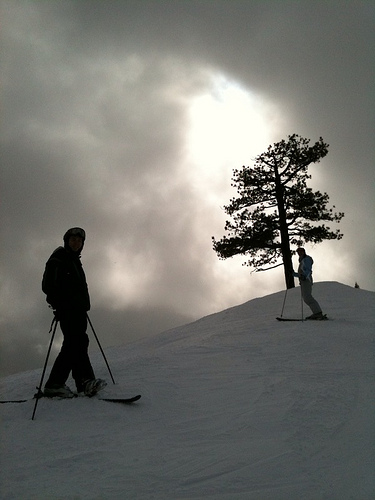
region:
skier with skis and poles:
[26, 219, 156, 425]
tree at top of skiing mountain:
[227, 140, 339, 288]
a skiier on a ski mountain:
[259, 242, 335, 329]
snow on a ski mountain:
[214, 399, 297, 466]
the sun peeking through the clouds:
[156, 69, 300, 198]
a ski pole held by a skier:
[20, 308, 76, 426]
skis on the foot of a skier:
[41, 381, 143, 411]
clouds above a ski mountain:
[126, 248, 195, 308]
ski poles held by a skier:
[277, 267, 310, 317]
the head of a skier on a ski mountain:
[58, 227, 93, 261]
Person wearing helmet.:
[50, 219, 98, 248]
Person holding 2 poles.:
[8, 369, 131, 387]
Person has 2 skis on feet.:
[57, 373, 163, 418]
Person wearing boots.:
[43, 372, 132, 399]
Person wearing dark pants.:
[54, 349, 132, 385]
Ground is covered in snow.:
[169, 407, 281, 495]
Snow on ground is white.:
[177, 400, 282, 471]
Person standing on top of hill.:
[274, 251, 346, 349]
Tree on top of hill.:
[242, 247, 342, 317]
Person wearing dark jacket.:
[39, 237, 111, 321]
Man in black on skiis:
[8, 212, 147, 413]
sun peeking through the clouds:
[185, 87, 274, 175]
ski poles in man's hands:
[15, 306, 123, 437]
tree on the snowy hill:
[208, 128, 353, 306]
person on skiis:
[264, 245, 336, 329]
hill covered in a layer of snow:
[116, 269, 373, 362]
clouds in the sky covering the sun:
[4, 30, 365, 277]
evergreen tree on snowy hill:
[201, 132, 342, 295]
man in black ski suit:
[30, 219, 111, 410]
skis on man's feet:
[1, 380, 175, 412]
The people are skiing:
[50, 203, 346, 399]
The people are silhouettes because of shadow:
[9, 199, 348, 413]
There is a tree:
[203, 134, 350, 300]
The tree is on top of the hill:
[211, 125, 359, 348]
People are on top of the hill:
[57, 184, 337, 392]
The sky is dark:
[9, 4, 362, 335]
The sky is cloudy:
[9, 9, 367, 346]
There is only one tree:
[196, 100, 334, 322]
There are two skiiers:
[38, 203, 330, 377]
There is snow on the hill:
[4, 261, 360, 487]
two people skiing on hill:
[10, 225, 328, 418]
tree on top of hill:
[209, 132, 345, 289]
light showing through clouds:
[162, 64, 337, 300]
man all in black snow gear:
[39, 225, 105, 400]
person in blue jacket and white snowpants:
[291, 247, 327, 319]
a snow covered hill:
[0, 279, 374, 498]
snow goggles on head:
[66, 225, 86, 239]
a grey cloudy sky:
[0, 0, 373, 377]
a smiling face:
[65, 233, 85, 252]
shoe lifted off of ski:
[78, 377, 116, 402]